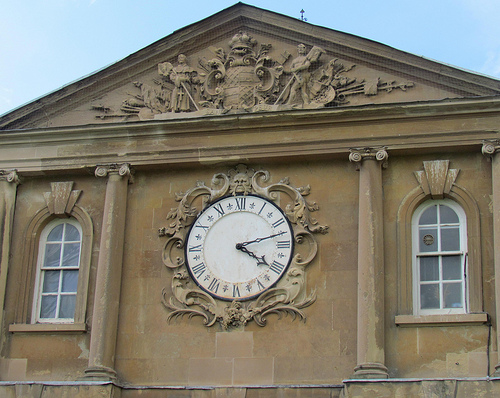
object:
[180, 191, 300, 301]
clock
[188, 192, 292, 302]
face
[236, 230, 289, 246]
hands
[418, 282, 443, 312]
window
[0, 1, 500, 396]
building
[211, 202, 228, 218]
numbers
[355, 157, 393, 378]
columns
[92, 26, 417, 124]
sculpture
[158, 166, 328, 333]
art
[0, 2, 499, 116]
sky